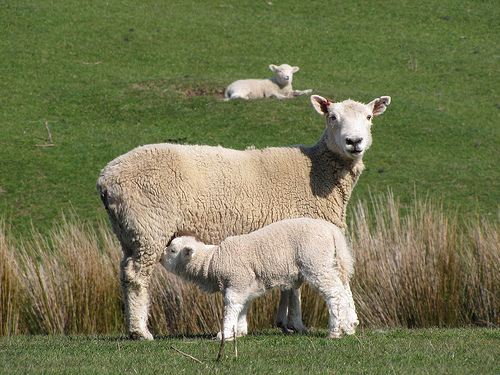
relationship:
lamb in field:
[222, 61, 312, 101] [13, 17, 483, 98]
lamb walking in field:
[158, 217, 361, 339] [1, 0, 498, 371]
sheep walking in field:
[98, 84, 391, 348] [1, 0, 498, 371]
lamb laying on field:
[222, 61, 312, 101] [7, 221, 485, 360]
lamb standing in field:
[222, 61, 312, 101] [5, 12, 445, 342]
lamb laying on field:
[222, 61, 312, 101] [0, 0, 498, 323]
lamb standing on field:
[158, 217, 361, 339] [1, 0, 498, 371]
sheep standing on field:
[98, 84, 391, 348] [1, 0, 498, 371]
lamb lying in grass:
[221, 59, 320, 105] [17, 9, 499, 330]